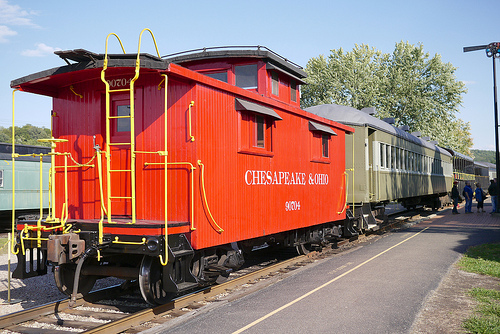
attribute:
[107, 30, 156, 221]
ladder — yellow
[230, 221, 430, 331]
line — white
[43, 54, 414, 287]
caboose — red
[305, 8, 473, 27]
sky — blue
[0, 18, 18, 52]
cloud — white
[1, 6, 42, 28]
cloud — white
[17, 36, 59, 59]
cloud — white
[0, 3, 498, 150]
sky — blue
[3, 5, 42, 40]
clouds — white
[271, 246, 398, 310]
line — white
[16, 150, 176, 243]
stand — iron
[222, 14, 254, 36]
clouds — white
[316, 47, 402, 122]
leaves — green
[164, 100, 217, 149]
handle — yellow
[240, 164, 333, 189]
text — white